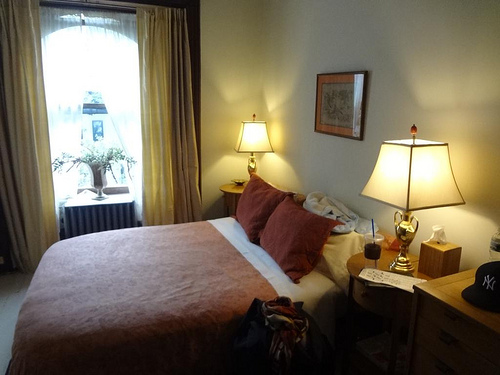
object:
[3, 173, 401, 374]
bed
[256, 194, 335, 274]
pillows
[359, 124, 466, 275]
lamp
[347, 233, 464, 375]
table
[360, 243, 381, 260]
cup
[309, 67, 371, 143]
painting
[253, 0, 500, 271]
wall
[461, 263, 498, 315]
cap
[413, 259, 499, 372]
drawer